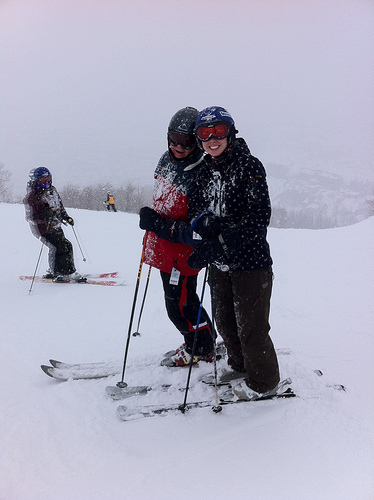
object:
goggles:
[196, 121, 232, 143]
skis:
[116, 377, 297, 422]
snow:
[0, 201, 373, 499]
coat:
[107, 197, 116, 209]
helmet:
[167, 106, 200, 147]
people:
[23, 166, 88, 283]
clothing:
[185, 137, 282, 394]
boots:
[213, 376, 296, 402]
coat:
[138, 151, 212, 274]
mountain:
[253, 163, 374, 228]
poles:
[177, 266, 209, 411]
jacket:
[184, 139, 272, 272]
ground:
[0, 202, 373, 496]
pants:
[206, 266, 281, 391]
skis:
[20, 274, 119, 286]